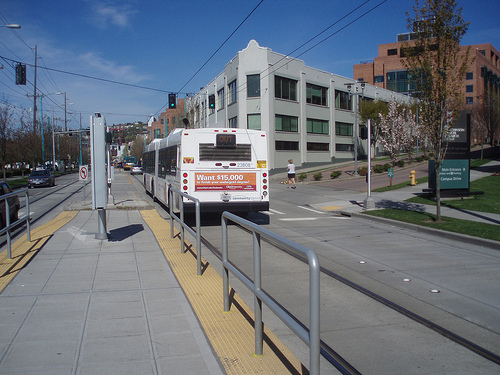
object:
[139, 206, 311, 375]
paint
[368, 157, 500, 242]
grass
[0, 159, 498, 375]
boulevard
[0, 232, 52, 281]
shadow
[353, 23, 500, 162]
brick building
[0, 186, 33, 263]
railing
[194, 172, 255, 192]
ad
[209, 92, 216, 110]
toilet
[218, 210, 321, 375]
railing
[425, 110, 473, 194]
sign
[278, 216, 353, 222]
line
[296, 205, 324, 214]
line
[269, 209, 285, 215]
line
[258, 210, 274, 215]
line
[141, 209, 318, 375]
curb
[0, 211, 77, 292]
curb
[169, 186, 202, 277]
railing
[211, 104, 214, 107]
light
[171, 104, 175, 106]
light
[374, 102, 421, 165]
flower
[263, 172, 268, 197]
taillights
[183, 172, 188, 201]
taillights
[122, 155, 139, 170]
bus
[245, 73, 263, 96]
window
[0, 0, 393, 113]
wires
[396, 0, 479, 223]
tree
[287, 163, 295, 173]
shirt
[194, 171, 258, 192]
banner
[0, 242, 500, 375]
track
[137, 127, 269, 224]
bus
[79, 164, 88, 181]
sign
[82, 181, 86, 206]
pole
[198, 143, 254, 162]
vents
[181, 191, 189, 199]
rear lights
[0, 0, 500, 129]
sky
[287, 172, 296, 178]
shorts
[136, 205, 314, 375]
edge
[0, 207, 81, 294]
edge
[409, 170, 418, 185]
fire hydrant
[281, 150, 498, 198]
sidewalk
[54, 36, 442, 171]
building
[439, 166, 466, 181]
letters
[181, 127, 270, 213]
back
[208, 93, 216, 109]
traffic light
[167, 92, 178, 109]
traffic light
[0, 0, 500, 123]
cloud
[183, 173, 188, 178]
light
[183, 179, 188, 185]
light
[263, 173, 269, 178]
light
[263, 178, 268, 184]
light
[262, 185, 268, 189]
light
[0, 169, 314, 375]
platform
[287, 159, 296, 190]
person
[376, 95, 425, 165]
tree branches